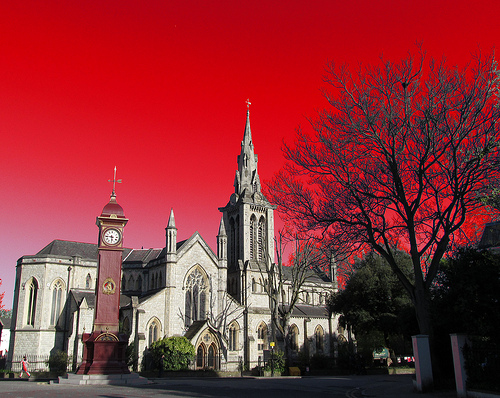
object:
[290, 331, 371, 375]
shadows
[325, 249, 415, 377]
tree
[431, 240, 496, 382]
tree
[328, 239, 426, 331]
leaves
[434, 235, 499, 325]
leaves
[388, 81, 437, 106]
ground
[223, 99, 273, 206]
steeple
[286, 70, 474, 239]
tree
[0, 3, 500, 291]
red sky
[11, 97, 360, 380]
church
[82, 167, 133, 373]
tower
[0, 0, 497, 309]
clouds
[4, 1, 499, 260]
sky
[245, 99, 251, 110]
cross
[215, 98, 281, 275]
church tower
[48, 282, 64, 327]
tall window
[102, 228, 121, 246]
clock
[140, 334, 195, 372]
bushes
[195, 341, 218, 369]
double doors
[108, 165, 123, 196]
cross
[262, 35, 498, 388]
large tree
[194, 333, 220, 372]
entrance